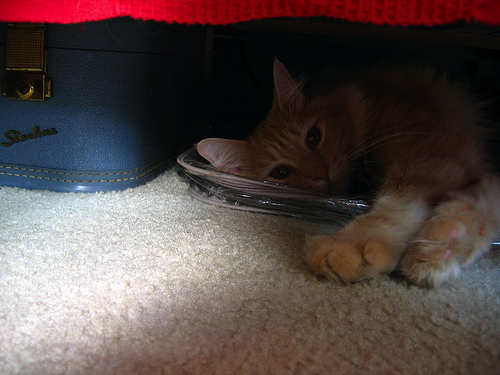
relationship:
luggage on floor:
[2, 19, 211, 193] [6, 129, 499, 373]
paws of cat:
[304, 202, 495, 285] [193, 55, 496, 288]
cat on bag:
[193, 55, 496, 288] [178, 136, 371, 222]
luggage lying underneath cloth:
[2, 19, 210, 194] [1, 0, 484, 27]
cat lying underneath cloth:
[193, 55, 496, 288] [1, 0, 484, 27]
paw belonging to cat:
[297, 209, 413, 285] [193, 55, 496, 288]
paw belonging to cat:
[397, 197, 484, 289] [193, 55, 496, 288]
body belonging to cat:
[373, 58, 483, 143] [193, 55, 496, 288]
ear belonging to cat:
[191, 135, 259, 180] [193, 55, 496, 288]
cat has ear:
[188, 45, 498, 288] [192, 131, 248, 174]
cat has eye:
[188, 45, 498, 288] [262, 156, 294, 181]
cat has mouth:
[193, 55, 496, 288] [319, 165, 353, 190]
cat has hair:
[188, 45, 498, 288] [370, 73, 479, 147]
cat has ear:
[188, 45, 498, 288] [262, 45, 305, 94]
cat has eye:
[188, 45, 498, 288] [299, 114, 328, 159]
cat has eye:
[188, 45, 498, 288] [261, 158, 301, 181]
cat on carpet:
[188, 45, 498, 288] [1, 191, 495, 371]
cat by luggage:
[193, 55, 496, 288] [2, 24, 249, 198]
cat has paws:
[193, 55, 496, 288] [293, 224, 476, 296]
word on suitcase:
[2, 120, 60, 154] [2, 25, 227, 197]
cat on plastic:
[188, 45, 498, 288] [170, 153, 371, 223]